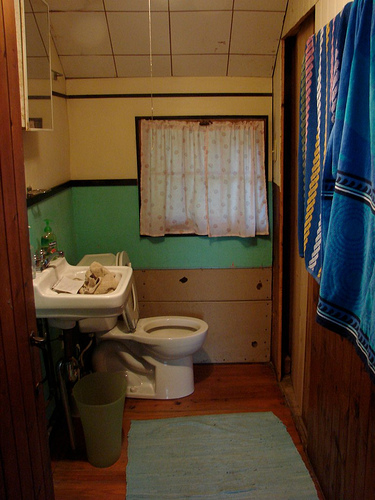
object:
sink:
[31, 255, 134, 334]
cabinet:
[13, 0, 55, 136]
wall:
[273, 0, 375, 500]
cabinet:
[130, 265, 274, 365]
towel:
[79, 261, 122, 295]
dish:
[27, 186, 51, 198]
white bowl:
[136, 315, 208, 401]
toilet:
[114, 249, 209, 399]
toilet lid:
[114, 250, 140, 333]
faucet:
[33, 254, 41, 278]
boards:
[125, 410, 324, 499]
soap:
[41, 218, 57, 261]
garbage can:
[72, 371, 129, 468]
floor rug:
[125, 411, 320, 499]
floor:
[49, 361, 324, 499]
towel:
[297, 9, 346, 287]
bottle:
[41, 218, 58, 260]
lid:
[43, 218, 53, 232]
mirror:
[23, 0, 54, 132]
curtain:
[137, 118, 270, 240]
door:
[303, 19, 375, 499]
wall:
[63, 81, 280, 366]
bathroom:
[0, 4, 373, 500]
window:
[132, 113, 271, 243]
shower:
[315, 0, 375, 374]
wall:
[22, 38, 78, 408]